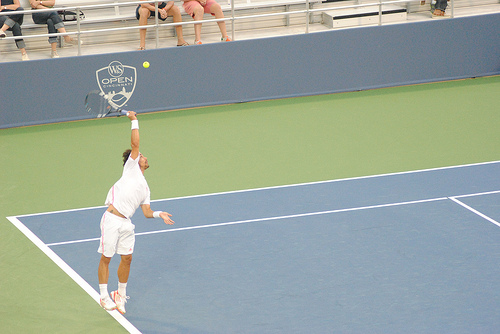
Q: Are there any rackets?
A: Yes, there is a racket.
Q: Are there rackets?
A: Yes, there is a racket.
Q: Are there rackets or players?
A: Yes, there is a racket.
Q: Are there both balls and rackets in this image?
A: Yes, there are both a racket and a ball.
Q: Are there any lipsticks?
A: No, there are no lipsticks.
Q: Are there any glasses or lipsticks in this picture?
A: No, there are no lipsticks or glasses.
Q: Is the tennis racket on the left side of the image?
A: Yes, the tennis racket is on the left of the image.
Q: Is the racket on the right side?
A: No, the racket is on the left of the image.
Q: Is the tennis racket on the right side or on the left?
A: The tennis racket is on the left of the image.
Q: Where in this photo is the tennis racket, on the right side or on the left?
A: The tennis racket is on the left of the image.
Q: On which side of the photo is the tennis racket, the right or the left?
A: The tennis racket is on the left of the image.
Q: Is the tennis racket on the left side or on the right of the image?
A: The tennis racket is on the left of the image.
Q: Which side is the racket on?
A: The racket is on the left of the image.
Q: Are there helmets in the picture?
A: No, there are no helmets.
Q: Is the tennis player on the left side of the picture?
A: Yes, the player is on the left of the image.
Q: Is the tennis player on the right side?
A: No, the player is on the left of the image.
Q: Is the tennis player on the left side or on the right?
A: The player is on the left of the image.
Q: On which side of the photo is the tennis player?
A: The player is on the left of the image.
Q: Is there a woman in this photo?
A: Yes, there are women.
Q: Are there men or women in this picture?
A: Yes, there are women.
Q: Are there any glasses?
A: No, there are no glasses.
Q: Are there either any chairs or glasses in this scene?
A: No, there are no glasses or chairs.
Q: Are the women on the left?
A: Yes, the women are on the left of the image.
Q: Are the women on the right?
A: No, the women are on the left of the image.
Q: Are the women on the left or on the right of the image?
A: The women are on the left of the image.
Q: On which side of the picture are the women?
A: The women are on the left of the image.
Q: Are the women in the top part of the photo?
A: Yes, the women are in the top of the image.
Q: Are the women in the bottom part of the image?
A: No, the women are in the top of the image.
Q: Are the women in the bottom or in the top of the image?
A: The women are in the top of the image.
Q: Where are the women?
A: The women are in the bleachers.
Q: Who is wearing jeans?
A: The women are wearing jeans.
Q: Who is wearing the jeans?
A: The women are wearing jeans.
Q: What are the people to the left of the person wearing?
A: The women are wearing jeans.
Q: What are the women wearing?
A: The women are wearing jeans.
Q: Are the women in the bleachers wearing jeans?
A: Yes, the women are wearing jeans.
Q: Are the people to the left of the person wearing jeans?
A: Yes, the women are wearing jeans.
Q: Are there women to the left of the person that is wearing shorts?
A: Yes, there are women to the left of the person.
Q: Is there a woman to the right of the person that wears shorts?
A: No, the women are to the left of the person.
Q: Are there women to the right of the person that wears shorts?
A: No, the women are to the left of the person.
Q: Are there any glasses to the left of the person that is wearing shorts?
A: No, there are women to the left of the person.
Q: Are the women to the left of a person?
A: Yes, the women are to the left of a person.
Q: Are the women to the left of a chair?
A: No, the women are to the left of a person.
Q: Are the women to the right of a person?
A: No, the women are to the left of a person.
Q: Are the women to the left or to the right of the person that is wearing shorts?
A: The women are to the left of the person.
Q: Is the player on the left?
A: Yes, the player is on the left of the image.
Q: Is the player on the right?
A: No, the player is on the left of the image.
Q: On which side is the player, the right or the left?
A: The player is on the left of the image.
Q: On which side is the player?
A: The player is on the left of the image.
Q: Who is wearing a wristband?
A: The player is wearing a wristband.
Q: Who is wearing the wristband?
A: The player is wearing a wristband.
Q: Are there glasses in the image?
A: No, there are no glasses.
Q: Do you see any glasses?
A: No, there are no glasses.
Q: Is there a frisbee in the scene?
A: No, there are no frisbees.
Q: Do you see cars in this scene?
A: No, there are no cars.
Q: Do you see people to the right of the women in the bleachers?
A: Yes, there is a person to the right of the women.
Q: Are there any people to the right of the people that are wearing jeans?
A: Yes, there is a person to the right of the women.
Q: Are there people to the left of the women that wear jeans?
A: No, the person is to the right of the women.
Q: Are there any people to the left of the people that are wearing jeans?
A: No, the person is to the right of the women.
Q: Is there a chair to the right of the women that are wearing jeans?
A: No, there is a person to the right of the women.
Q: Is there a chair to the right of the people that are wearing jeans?
A: No, there is a person to the right of the women.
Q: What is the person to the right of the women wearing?
A: The person is wearing shorts.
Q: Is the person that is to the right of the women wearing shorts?
A: Yes, the person is wearing shorts.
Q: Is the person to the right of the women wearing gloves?
A: No, the person is wearing shorts.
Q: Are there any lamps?
A: No, there are no lamps.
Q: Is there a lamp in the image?
A: No, there are no lamps.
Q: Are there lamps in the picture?
A: No, there are no lamps.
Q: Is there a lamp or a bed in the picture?
A: No, there are no lamps or beds.